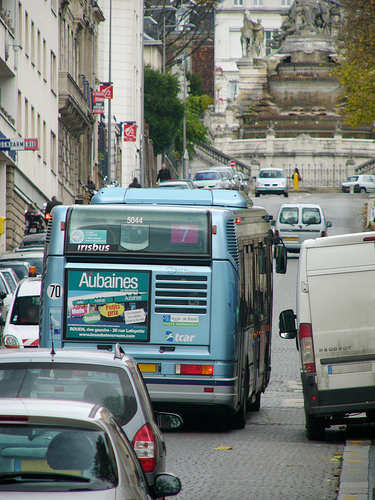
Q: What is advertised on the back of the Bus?
A: Aubaines.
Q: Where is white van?
A: To the right of the bus.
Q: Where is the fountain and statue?
A: At the end of the street.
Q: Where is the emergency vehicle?
A: To the left and in front of the bus.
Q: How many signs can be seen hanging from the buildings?
A: 4.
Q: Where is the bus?
A: On the street.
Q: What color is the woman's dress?
A: Yellow.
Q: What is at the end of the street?
A: A statue.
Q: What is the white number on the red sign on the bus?
A: 7.